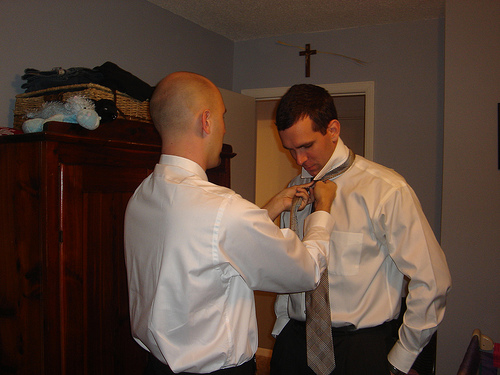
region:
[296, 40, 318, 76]
cross hanging above doorway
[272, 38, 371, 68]
dried palm frond behind cross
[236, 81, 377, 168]
white wooden frame around doorway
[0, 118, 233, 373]
wooden armoire against wall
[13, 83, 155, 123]
wicker basket on top of armoire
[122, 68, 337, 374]
man standing in front of armoire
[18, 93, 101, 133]
stuffed animal on top of armoire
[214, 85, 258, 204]
door is open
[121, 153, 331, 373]
man wearing a white dress shirt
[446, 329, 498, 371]
playpen visible to the right of man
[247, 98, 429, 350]
a man with brown hair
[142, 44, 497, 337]
two men standing inside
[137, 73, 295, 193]
a man with no hair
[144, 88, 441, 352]
two men wearing white shirts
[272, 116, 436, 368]
a man weraing a tie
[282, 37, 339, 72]
a cross on the wall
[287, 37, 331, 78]
a wall with a cross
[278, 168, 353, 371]
man tying another mans necktie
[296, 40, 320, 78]
Cross on the top of a wall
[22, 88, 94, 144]
teddy bear on a shelf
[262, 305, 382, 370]
man wearing black pants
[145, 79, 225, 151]
man with a bald head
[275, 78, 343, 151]
man with brown hair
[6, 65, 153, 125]
basket on a shelf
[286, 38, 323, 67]
cross nailed to a wall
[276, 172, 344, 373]
man wearing a necktie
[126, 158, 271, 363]
man wearing a white shirt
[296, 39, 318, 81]
cross on the wall over the door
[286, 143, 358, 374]
gray plaid tie being put on the man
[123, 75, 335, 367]
man tying a tie for another man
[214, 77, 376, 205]
opened doorway to the hallway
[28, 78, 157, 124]
basket on top of an armoir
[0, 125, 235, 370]
dark cherry wood armoir dresser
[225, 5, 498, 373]
light blue painted walls in the bedroom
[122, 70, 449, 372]
two men preparing for a formal event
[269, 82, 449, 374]
the man is looking down at his tie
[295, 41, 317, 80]
wooden cross on the wall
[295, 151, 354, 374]
gray plaid tie around the man's neck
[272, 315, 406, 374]
the man is wearing black pants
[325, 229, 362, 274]
white pocket on the man's left chest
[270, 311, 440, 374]
the man has his hands in his pocket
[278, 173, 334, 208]
man's hands tying a tie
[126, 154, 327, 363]
long white sleeve shirt for a special occasion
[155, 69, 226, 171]
the man has a shaved head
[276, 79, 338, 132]
the man has dark brown hair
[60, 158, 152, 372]
cabinet to the dresser armoir